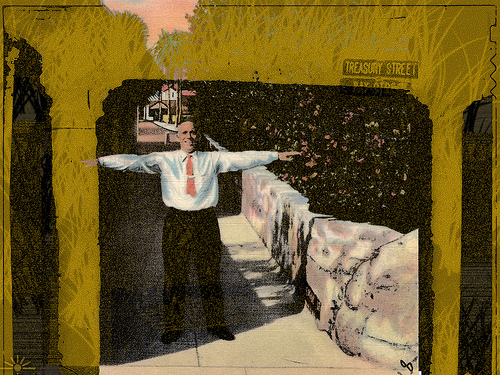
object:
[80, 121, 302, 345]
man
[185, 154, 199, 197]
tie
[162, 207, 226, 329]
pants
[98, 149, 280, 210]
shirt